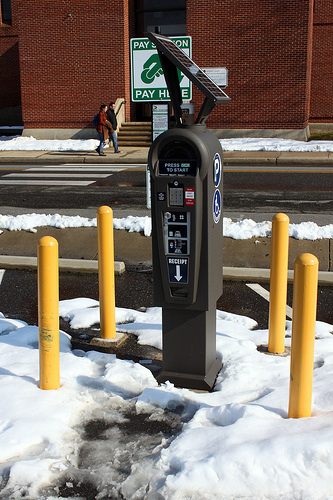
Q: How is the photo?
A: Clear.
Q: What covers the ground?
A: Snow.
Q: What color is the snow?
A: White.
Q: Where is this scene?
A: Street.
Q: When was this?
A: Daytime.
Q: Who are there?
A: People.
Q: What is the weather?
A: Sunny.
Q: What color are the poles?
A: Yellow.